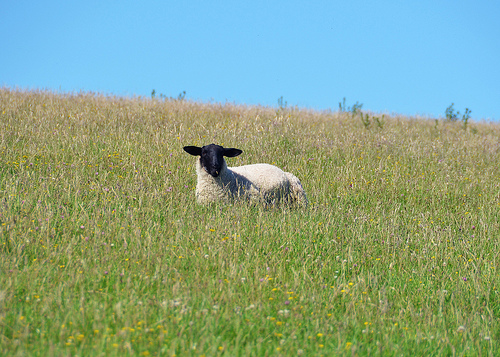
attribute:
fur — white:
[188, 166, 309, 216]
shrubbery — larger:
[337, 96, 475, 121]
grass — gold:
[9, 89, 461, 168]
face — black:
[175, 137, 239, 177]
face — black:
[186, 137, 232, 169]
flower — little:
[357, 313, 374, 330]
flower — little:
[132, 314, 150, 331]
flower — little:
[271, 300, 292, 321]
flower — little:
[370, 251, 385, 265]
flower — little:
[121, 251, 133, 265]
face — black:
[198, 141, 228, 181]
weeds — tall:
[6, 77, 498, 132]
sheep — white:
[179, 136, 311, 212]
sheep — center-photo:
[176, 136, 318, 208]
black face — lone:
[187, 137, 252, 166]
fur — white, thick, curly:
[192, 166, 309, 211]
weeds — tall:
[418, 90, 486, 141]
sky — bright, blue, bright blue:
[4, 2, 498, 114]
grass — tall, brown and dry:
[0, 87, 499, 354]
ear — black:
[181, 145, 205, 157]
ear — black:
[215, 145, 242, 159]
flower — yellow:
[214, 341, 231, 353]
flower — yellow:
[72, 329, 87, 344]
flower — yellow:
[60, 333, 72, 351]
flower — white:
[275, 304, 290, 319]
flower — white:
[455, 322, 471, 332]